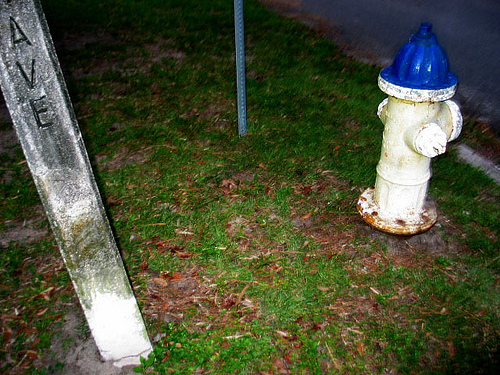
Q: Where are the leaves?
A: Ground.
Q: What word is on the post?
A: Ave.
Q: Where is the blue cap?
A: On the fire hydrant.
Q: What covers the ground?
A: Grass.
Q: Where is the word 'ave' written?
A: On the concrete pillar.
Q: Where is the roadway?
A: In the upper right corner.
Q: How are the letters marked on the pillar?
A: Indented.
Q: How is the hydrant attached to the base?
A: With rusty bolts.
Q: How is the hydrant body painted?
A: With white paint.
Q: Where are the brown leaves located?
A: On the ground.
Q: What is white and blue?
A: The hydrant.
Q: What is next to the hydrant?
A: The street.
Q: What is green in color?
A: The grass.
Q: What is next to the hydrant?
A: A pole.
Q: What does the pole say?
A: Ave.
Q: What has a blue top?
A: The hydrant.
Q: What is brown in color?
A: The ground.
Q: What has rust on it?
A: The hydrant.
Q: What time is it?
A: Night.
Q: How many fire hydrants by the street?
A: One.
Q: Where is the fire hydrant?
A: By the street.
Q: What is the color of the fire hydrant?
A: White and blue.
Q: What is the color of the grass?
A: Green.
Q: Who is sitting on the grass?
A: No one.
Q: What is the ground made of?
A: Soil and grass.